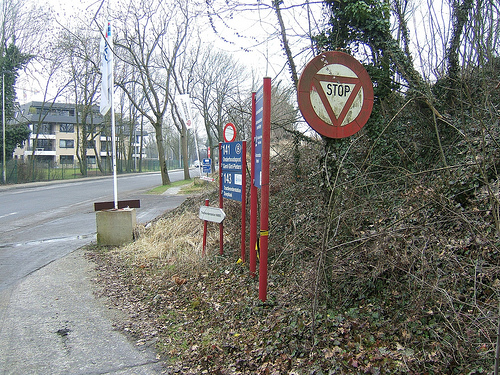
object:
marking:
[0, 210, 17, 218]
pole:
[257, 76, 272, 306]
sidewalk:
[0, 240, 157, 374]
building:
[15, 99, 150, 170]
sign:
[196, 204, 226, 226]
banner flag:
[175, 93, 196, 131]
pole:
[191, 125, 203, 176]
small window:
[66, 122, 74, 132]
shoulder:
[6, 245, 189, 374]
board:
[217, 142, 245, 204]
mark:
[55, 325, 72, 340]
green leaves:
[352, 10, 376, 23]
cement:
[93, 209, 137, 248]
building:
[1, 99, 149, 171]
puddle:
[0, 243, 13, 251]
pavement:
[0, 167, 197, 374]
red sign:
[222, 122, 237, 143]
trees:
[0, 43, 39, 173]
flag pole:
[105, 19, 118, 214]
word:
[326, 82, 350, 97]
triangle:
[311, 73, 363, 126]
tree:
[310, 0, 438, 126]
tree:
[440, 0, 472, 103]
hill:
[111, 57, 499, 373]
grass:
[105, 58, 499, 374]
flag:
[98, 21, 111, 117]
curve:
[0, 181, 98, 372]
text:
[218, 154, 240, 169]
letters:
[196, 210, 220, 219]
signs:
[293, 49, 375, 141]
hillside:
[145, 56, 499, 231]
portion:
[40, 192, 74, 209]